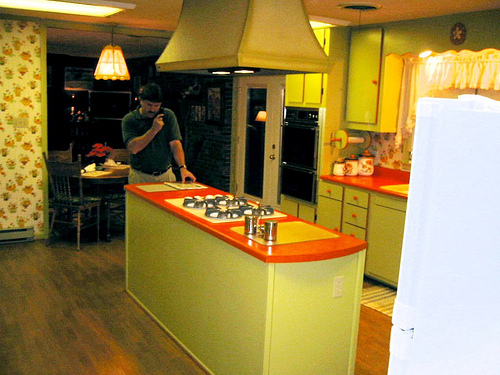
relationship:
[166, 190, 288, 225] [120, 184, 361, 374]
stove on island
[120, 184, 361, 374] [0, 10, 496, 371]
island in middle of kitchen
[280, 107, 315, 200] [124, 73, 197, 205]
double oven to right of man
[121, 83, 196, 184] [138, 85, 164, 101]
man has black hair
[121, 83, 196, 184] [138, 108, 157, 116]
man has mustache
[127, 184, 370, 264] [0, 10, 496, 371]
counter in kitchen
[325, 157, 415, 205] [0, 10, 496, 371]
counter in kitchen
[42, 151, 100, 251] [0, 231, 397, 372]
chair on ground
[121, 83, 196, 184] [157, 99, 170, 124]
man talking on cell phone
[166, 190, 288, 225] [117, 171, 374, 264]
stove on counter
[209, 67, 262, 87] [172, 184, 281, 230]
lights above stove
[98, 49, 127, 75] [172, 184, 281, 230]
light above stove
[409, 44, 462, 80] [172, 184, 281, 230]
lights above stove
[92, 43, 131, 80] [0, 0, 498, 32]
light hanging from ceiling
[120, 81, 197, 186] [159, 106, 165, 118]
man talking on cell phone